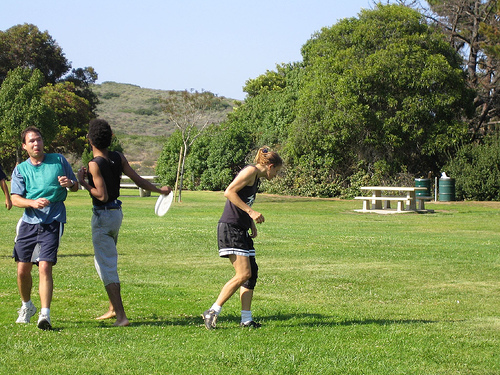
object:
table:
[353, 186, 427, 201]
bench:
[353, 196, 413, 212]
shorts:
[217, 222, 256, 258]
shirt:
[219, 165, 262, 231]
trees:
[153, 2, 499, 204]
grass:
[0, 187, 500, 375]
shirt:
[10, 153, 77, 225]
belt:
[92, 206, 121, 216]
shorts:
[13, 216, 64, 267]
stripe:
[15, 216, 24, 242]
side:
[12, 218, 24, 262]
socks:
[241, 310, 253, 324]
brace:
[241, 256, 259, 290]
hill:
[76, 80, 241, 177]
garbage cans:
[414, 172, 455, 202]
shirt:
[86, 151, 123, 206]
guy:
[10, 125, 79, 330]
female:
[77, 119, 173, 327]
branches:
[349, 133, 383, 159]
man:
[76, 118, 171, 327]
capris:
[91, 206, 124, 287]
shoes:
[200, 309, 219, 331]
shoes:
[37, 311, 52, 329]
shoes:
[15, 304, 37, 324]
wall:
[100, 104, 170, 149]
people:
[0, 118, 284, 331]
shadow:
[51, 313, 464, 332]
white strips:
[218, 248, 255, 258]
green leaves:
[0, 0, 499, 203]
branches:
[450, 0, 498, 142]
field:
[0, 188, 500, 374]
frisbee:
[155, 190, 174, 217]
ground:
[0, 187, 500, 375]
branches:
[345, 30, 415, 59]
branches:
[307, 88, 354, 114]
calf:
[218, 277, 235, 298]